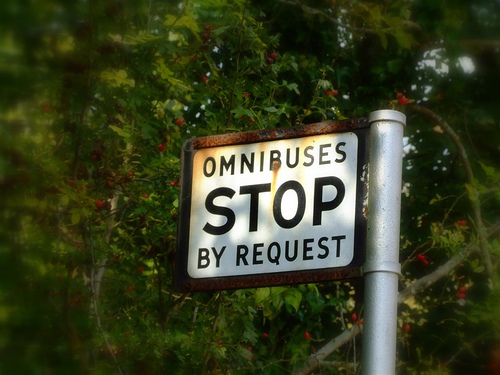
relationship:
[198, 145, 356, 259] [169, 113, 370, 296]
letters on sign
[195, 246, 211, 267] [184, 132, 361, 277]
letter on sign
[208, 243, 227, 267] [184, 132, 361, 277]
letter on sign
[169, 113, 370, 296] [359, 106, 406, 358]
sign mounted on pole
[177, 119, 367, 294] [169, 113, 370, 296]
frame around sign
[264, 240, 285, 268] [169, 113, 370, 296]
letter q on sign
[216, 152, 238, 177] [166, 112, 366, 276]
letter on sign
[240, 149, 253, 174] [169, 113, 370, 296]
n on sign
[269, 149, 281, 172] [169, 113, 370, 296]
letter on sign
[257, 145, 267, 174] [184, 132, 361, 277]
letter on sign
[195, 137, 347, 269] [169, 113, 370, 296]
word on sign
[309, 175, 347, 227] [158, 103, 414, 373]
p on sign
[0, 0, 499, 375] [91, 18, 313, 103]
leaf on tree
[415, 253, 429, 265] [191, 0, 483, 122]
berry on tree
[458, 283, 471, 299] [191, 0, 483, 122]
red berry on tree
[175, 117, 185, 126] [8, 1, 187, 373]
berry on tree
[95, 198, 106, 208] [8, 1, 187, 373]
red berry on tree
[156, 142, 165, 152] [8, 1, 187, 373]
red berry on tree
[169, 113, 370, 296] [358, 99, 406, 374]
sign mounted on pole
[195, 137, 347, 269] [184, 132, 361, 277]
word on sign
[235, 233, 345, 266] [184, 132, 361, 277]
word on sign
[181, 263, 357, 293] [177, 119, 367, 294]
rust spot on frame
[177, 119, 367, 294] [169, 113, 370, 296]
frame on sign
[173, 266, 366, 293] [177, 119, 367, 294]
rust spot on frame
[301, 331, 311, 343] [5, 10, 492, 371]
berry on tree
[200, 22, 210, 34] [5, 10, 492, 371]
berry on tree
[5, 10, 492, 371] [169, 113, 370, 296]
tree behind sign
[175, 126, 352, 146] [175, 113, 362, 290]
rust on sign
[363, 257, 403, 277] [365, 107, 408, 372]
bracket on pole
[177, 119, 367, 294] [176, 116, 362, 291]
frame covered in rust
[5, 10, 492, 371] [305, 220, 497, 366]
tree has branch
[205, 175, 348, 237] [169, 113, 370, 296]
stop on sign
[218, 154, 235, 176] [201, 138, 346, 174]
letter in word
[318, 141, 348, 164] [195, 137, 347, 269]
letters in word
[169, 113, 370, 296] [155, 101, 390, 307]
sign mounted on pole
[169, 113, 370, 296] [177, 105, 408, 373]
sign mounted on sign post